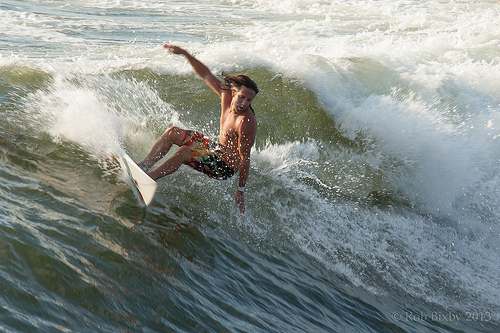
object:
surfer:
[134, 41, 259, 213]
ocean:
[1, 1, 498, 331]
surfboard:
[114, 148, 158, 207]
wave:
[251, 0, 495, 329]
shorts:
[178, 128, 237, 182]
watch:
[237, 185, 247, 193]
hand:
[234, 190, 245, 214]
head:
[227, 76, 257, 115]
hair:
[222, 71, 259, 93]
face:
[233, 89, 256, 113]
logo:
[133, 179, 141, 190]